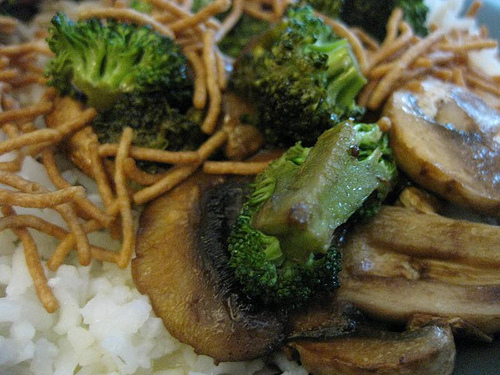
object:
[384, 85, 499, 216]
mushroom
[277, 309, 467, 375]
mushroom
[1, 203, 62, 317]
noodle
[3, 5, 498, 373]
fry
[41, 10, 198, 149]
broccoli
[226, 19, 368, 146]
broccoli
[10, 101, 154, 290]
topping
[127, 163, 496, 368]
mushroom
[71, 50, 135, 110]
underside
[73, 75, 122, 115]
stem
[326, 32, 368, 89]
stem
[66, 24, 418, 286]
vegetable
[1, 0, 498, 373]
meal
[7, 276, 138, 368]
rice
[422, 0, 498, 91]
rice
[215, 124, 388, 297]
broccoli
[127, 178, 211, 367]
zucchini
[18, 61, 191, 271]
fried noodles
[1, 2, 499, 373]
entree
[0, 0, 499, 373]
plate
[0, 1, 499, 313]
topping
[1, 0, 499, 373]
dish